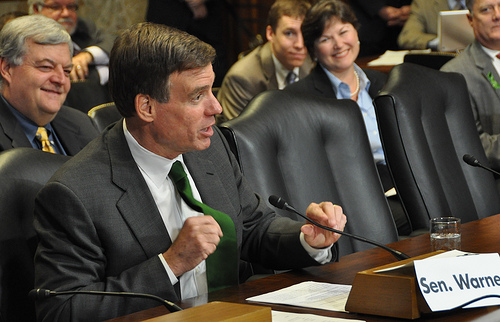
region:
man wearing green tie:
[168, 160, 243, 290]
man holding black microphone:
[266, 195, 409, 260]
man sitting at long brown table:
[102, 214, 499, 320]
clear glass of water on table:
[428, 214, 460, 254]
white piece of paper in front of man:
[246, 276, 353, 312]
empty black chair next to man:
[217, 85, 401, 272]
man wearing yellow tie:
[35, 126, 55, 153]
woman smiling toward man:
[281, 0, 416, 236]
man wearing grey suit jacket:
[31, 118, 343, 320]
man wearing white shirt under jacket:
[121, 118, 217, 300]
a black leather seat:
[245, 110, 377, 190]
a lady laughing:
[301, 0, 366, 75]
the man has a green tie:
[160, 165, 245, 292]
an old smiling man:
[0, 20, 80, 125]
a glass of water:
[430, 215, 455, 252]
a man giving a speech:
[62, 11, 294, 311]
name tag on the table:
[409, 250, 499, 309]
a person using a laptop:
[394, 0, 467, 49]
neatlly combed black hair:
[105, 28, 225, 158]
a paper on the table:
[245, 280, 360, 306]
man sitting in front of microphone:
[18, 19, 317, 307]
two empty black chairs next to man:
[103, 30, 496, 291]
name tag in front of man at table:
[36, 80, 494, 317]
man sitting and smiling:
[2, 16, 114, 158]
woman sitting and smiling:
[284, 7, 409, 172]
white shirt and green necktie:
[87, 111, 262, 297]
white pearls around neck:
[304, 8, 401, 138]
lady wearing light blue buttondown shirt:
[294, 10, 413, 195]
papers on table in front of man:
[53, 90, 393, 321]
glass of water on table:
[374, 176, 478, 284]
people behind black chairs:
[250, 3, 496, 258]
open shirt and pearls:
[327, 65, 373, 110]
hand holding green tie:
[166, 157, 240, 296]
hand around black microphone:
[267, 190, 402, 255]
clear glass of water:
[428, 214, 463, 251]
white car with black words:
[416, 254, 498, 311]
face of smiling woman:
[309, 1, 361, 68]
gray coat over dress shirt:
[40, 126, 297, 313]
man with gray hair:
[3, 21, 70, 117]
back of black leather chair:
[386, 60, 496, 231]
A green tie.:
[168, 161, 240, 291]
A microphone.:
[264, 192, 409, 259]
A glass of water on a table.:
[429, 213, 462, 251]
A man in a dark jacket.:
[34, 24, 341, 320]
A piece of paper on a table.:
[243, 276, 354, 311]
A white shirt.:
[122, 118, 210, 303]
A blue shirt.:
[323, 63, 387, 163]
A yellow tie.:
[33, 128, 55, 153]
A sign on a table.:
[412, 250, 499, 312]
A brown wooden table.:
[90, 208, 497, 320]